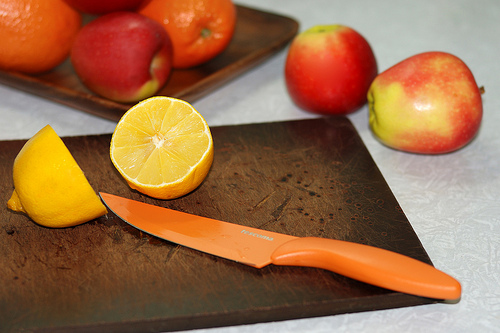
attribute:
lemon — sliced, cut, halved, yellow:
[109, 95, 214, 198]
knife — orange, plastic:
[98, 193, 462, 300]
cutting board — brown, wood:
[3, 117, 443, 331]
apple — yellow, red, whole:
[72, 12, 170, 104]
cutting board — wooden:
[2, 2, 297, 115]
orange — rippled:
[139, 1, 236, 69]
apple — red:
[285, 25, 377, 116]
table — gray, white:
[2, 2, 498, 331]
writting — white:
[239, 229, 272, 242]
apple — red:
[368, 52, 486, 155]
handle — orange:
[273, 236, 460, 302]